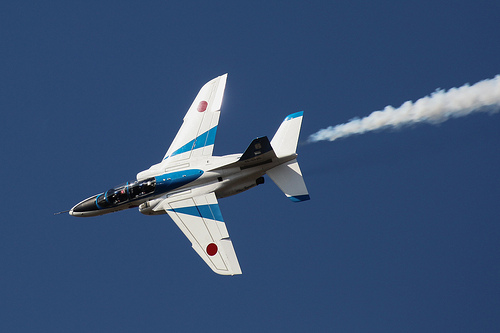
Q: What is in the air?
A: A jet.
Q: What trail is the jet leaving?
A: Vapor.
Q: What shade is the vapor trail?
A: White.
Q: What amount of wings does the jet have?
A: Two.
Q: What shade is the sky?
A: Blue.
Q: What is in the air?
A: A plane.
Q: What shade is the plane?
A: White and blue.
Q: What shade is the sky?
A: Dark blue.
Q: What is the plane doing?
A: Flying.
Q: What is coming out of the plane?
A: Smoke.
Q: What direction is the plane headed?
A: Downward.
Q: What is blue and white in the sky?
A: Plane.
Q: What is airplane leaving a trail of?
A: Smoke.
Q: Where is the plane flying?
A: Sky.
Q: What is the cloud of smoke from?
A: Plane.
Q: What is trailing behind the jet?
A: Smoke.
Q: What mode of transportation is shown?
A: Plane.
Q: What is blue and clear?
A: Sky.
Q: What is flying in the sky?
A: Jet.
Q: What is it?
A: A jet fighter.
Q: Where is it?
A: In the sky.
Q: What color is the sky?
A: Blue.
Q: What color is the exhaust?
A: White.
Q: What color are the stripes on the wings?
A: Blue.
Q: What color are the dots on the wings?
A: Red.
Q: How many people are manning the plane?
A: Two.